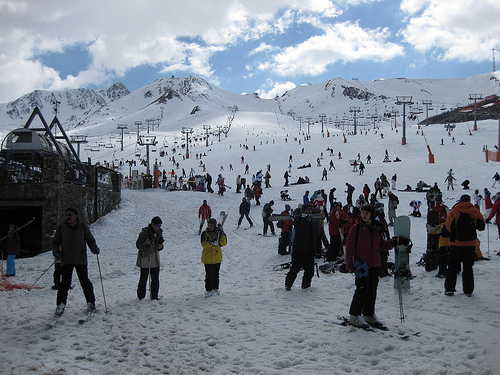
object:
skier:
[285, 203, 331, 290]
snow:
[241, 125, 496, 186]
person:
[135, 216, 164, 302]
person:
[54, 207, 100, 315]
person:
[438, 193, 485, 297]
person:
[344, 204, 400, 329]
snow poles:
[393, 249, 405, 325]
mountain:
[275, 72, 500, 133]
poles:
[138, 105, 239, 174]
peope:
[261, 146, 499, 334]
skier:
[366, 154, 372, 164]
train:
[0, 106, 120, 253]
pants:
[349, 267, 381, 317]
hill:
[0, 68, 496, 254]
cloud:
[244, 0, 333, 28]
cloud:
[87, 39, 222, 86]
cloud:
[0, 56, 64, 107]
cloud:
[255, 18, 405, 78]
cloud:
[400, 0, 498, 64]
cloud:
[1, 0, 61, 49]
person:
[0, 223, 20, 275]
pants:
[6, 254, 15, 275]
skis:
[393, 215, 412, 288]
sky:
[1, 0, 500, 106]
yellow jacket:
[201, 226, 228, 265]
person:
[200, 219, 228, 298]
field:
[0, 122, 497, 375]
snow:
[45, 70, 397, 133]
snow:
[0, 191, 500, 373]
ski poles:
[27, 253, 109, 314]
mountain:
[0, 89, 105, 130]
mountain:
[61, 74, 241, 134]